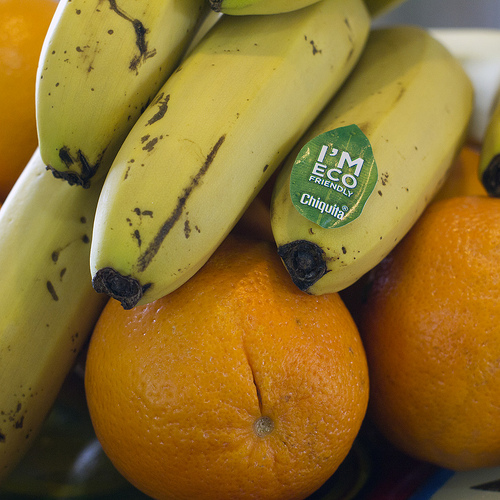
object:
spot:
[42, 275, 62, 305]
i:
[312, 144, 332, 164]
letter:
[308, 162, 325, 179]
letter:
[342, 175, 359, 190]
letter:
[338, 150, 361, 176]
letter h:
[308, 195, 317, 207]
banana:
[476, 80, 499, 201]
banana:
[46, 51, 496, 259]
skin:
[221, 60, 283, 101]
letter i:
[317, 144, 329, 163]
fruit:
[0, 147, 111, 481]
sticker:
[289, 123, 379, 229]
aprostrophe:
[329, 148, 339, 158]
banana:
[200, 0, 321, 20]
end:
[279, 240, 324, 288]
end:
[90, 264, 145, 312]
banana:
[28, 0, 209, 190]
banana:
[88, 0, 372, 311]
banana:
[267, 26, 477, 296]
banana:
[0, 141, 110, 468]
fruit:
[89, 3, 369, 307]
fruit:
[33, 0, 215, 187]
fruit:
[85, 234, 369, 497]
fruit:
[362, 196, 497, 467]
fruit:
[4, 142, 104, 498]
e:
[311, 161, 327, 177]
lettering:
[341, 173, 358, 190]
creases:
[239, 343, 269, 429]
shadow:
[367, 32, 407, 71]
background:
[441, 0, 484, 52]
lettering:
[300, 194, 310, 205]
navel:
[255, 410, 274, 440]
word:
[299, 193, 345, 221]